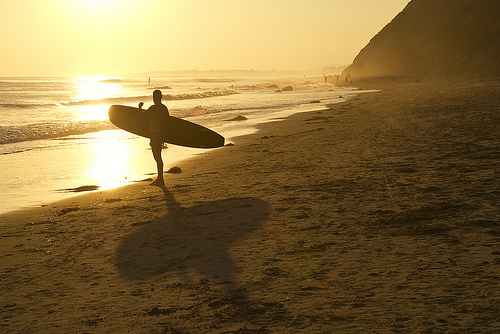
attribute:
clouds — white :
[4, 0, 413, 82]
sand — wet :
[173, 259, 233, 289]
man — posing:
[137, 88, 169, 185]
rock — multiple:
[223, 107, 246, 122]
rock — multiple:
[163, 160, 180, 173]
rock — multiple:
[281, 81, 294, 92]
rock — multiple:
[263, 80, 277, 91]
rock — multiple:
[273, 87, 280, 94]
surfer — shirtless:
[136, 87, 178, 192]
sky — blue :
[0, 0, 409, 218]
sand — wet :
[286, 160, 481, 307]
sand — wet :
[0, 102, 320, 211]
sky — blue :
[167, 12, 343, 48]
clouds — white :
[23, 8, 46, 26]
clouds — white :
[43, 21, 92, 46]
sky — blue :
[174, 12, 326, 50]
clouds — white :
[158, 8, 199, 22]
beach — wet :
[3, 87, 475, 332]